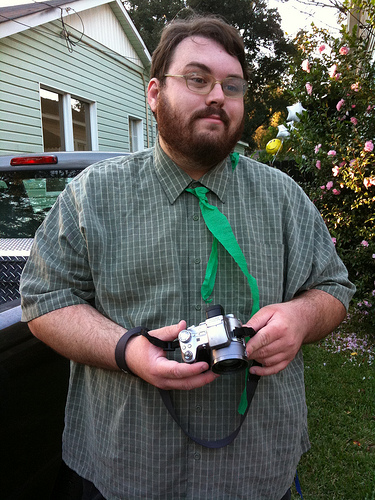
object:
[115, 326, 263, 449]
strap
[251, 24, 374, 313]
rose tree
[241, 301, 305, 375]
hand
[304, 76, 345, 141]
roses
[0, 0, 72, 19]
part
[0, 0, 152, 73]
roof top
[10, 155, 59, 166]
red light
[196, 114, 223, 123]
mouth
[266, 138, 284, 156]
yellow flower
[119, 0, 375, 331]
bush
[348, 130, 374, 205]
flowers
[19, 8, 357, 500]
man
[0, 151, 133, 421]
truck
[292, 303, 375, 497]
grass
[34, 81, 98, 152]
window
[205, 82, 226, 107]
nose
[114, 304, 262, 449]
camera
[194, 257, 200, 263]
buttons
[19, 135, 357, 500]
shirt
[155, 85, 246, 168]
beard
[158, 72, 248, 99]
eyeglasses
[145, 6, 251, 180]
head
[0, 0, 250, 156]
building